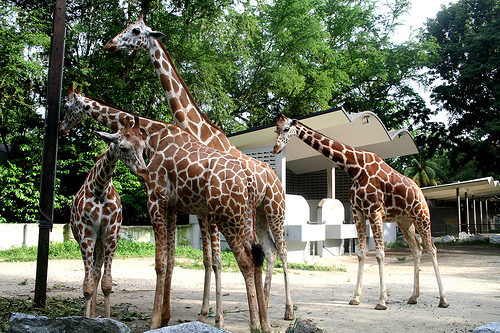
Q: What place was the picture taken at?
A: It was taken at the zoo.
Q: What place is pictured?
A: It is a zoo.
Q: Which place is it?
A: It is a zoo.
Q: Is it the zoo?
A: Yes, it is the zoo.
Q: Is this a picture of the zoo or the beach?
A: It is showing the zoo.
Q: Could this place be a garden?
A: No, it is a zoo.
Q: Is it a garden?
A: No, it is a zoo.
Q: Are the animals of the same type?
A: Yes, all the animals are giraffes.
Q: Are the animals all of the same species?
A: Yes, all the animals are giraffes.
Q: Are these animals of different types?
A: No, all the animals are giraffes.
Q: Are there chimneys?
A: No, there are no chimneys.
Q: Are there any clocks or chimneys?
A: No, there are no chimneys or clocks.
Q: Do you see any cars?
A: No, there are no cars.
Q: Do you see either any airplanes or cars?
A: No, there are no cars or airplanes.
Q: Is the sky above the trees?
A: Yes, the sky is above the trees.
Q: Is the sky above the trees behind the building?
A: Yes, the sky is above the trees.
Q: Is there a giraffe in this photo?
A: Yes, there are giraffes.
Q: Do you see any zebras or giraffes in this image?
A: Yes, there are giraffes.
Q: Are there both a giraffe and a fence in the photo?
A: Yes, there are both a giraffe and a fence.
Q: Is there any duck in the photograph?
A: No, there are no ducks.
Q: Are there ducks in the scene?
A: No, there are no ducks.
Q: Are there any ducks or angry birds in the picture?
A: No, there are no ducks or angry birds.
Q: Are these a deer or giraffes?
A: These are giraffes.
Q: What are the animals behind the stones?
A: The animals are giraffes.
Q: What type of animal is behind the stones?
A: The animals are giraffes.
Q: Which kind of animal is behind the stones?
A: The animals are giraffes.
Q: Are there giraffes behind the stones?
A: Yes, there are giraffes behind the stones.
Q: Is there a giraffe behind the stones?
A: Yes, there are giraffes behind the stones.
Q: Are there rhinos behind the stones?
A: No, there are giraffes behind the stones.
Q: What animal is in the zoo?
A: The giraffes are in the zoo.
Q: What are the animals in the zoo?
A: The animals are giraffes.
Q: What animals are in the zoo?
A: The animals are giraffes.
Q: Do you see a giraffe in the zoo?
A: Yes, there are giraffes in the zoo.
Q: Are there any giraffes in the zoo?
A: Yes, there are giraffes in the zoo.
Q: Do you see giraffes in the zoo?
A: Yes, there are giraffes in the zoo.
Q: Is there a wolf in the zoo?
A: No, there are giraffes in the zoo.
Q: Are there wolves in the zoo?
A: No, there are giraffes in the zoo.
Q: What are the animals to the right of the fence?
A: The animals are giraffes.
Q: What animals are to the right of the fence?
A: The animals are giraffes.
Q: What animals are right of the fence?
A: The animals are giraffes.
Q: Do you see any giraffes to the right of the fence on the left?
A: Yes, there are giraffes to the right of the fence.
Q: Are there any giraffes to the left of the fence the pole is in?
A: No, the giraffes are to the right of the fence.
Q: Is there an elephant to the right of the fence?
A: No, there are giraffes to the right of the fence.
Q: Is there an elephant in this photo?
A: No, there are no elephants.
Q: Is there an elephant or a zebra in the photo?
A: No, there are no elephants or zebras.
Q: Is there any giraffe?
A: Yes, there is a giraffe.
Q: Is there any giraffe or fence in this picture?
A: Yes, there is a giraffe.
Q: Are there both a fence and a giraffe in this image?
A: Yes, there are both a giraffe and a fence.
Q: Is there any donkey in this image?
A: No, there are no donkeys.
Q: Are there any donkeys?
A: No, there are no donkeys.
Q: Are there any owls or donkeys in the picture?
A: No, there are no donkeys or owls.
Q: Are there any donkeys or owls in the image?
A: No, there are no donkeys or owls.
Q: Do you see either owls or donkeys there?
A: No, there are no donkeys or owls.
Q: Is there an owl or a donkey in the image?
A: No, there are no donkeys or owls.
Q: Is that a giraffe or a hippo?
A: That is a giraffe.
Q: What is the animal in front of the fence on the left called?
A: The animal is a giraffe.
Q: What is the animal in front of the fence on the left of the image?
A: The animal is a giraffe.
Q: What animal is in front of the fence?
A: The animal is a giraffe.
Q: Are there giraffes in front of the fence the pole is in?
A: Yes, there is a giraffe in front of the fence.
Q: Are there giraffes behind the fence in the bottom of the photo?
A: No, the giraffe is in front of the fence.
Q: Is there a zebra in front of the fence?
A: No, there is a giraffe in front of the fence.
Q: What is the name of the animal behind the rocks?
A: The animal is a giraffe.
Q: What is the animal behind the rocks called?
A: The animal is a giraffe.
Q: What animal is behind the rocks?
A: The animal is a giraffe.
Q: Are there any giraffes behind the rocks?
A: Yes, there is a giraffe behind the rocks.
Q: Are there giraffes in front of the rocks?
A: No, the giraffe is behind the rocks.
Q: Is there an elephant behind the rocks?
A: No, there is a giraffe behind the rocks.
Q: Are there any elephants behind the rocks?
A: No, there is a giraffe behind the rocks.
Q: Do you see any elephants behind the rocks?
A: No, there is a giraffe behind the rocks.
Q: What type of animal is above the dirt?
A: The animal is a giraffe.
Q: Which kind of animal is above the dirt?
A: The animal is a giraffe.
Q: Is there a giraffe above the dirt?
A: Yes, there is a giraffe above the dirt.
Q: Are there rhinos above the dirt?
A: No, there is a giraffe above the dirt.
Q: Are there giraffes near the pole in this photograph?
A: Yes, there is a giraffe near the pole.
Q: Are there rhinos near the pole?
A: No, there is a giraffe near the pole.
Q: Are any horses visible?
A: No, there are no horses.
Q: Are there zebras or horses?
A: No, there are no horses or zebras.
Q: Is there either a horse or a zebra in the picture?
A: No, there are no horses or zebras.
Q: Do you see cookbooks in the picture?
A: No, there are no cookbooks.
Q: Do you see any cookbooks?
A: No, there are no cookbooks.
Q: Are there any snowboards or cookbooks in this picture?
A: No, there are no cookbooks or snowboards.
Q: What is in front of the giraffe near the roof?
A: The rocks are in front of the giraffe.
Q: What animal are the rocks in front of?
A: The rocks are in front of the giraffe.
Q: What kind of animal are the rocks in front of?
A: The rocks are in front of the giraffe.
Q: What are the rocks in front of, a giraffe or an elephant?
A: The rocks are in front of a giraffe.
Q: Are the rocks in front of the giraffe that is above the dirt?
A: Yes, the rocks are in front of the giraffe.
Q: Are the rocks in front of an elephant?
A: No, the rocks are in front of the giraffe.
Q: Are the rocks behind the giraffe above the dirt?
A: No, the rocks are in front of the giraffe.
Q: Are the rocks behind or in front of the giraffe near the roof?
A: The rocks are in front of the giraffe.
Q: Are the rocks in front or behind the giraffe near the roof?
A: The rocks are in front of the giraffe.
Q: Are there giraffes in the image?
A: Yes, there is a giraffe.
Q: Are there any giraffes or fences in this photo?
A: Yes, there is a giraffe.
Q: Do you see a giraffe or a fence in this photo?
A: Yes, there is a giraffe.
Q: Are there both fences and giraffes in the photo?
A: Yes, there are both a giraffe and a fence.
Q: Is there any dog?
A: No, there are no dogs.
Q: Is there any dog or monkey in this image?
A: No, there are no dogs or monkeys.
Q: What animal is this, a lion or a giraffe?
A: This is a giraffe.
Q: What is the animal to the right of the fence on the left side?
A: The animal is a giraffe.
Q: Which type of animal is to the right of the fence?
A: The animal is a giraffe.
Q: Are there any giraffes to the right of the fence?
A: Yes, there is a giraffe to the right of the fence.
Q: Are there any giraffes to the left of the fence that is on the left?
A: No, the giraffe is to the right of the fence.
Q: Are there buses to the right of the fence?
A: No, there is a giraffe to the right of the fence.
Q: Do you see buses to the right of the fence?
A: No, there is a giraffe to the right of the fence.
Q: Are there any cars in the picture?
A: No, there are no cars.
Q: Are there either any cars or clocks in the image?
A: No, there are no cars or clocks.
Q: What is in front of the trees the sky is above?
A: The building is in front of the trees.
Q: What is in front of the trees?
A: The building is in front of the trees.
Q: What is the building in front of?
A: The building is in front of the trees.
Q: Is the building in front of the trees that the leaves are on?
A: Yes, the building is in front of the trees.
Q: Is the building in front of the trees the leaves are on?
A: Yes, the building is in front of the trees.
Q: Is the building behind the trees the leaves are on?
A: No, the building is in front of the trees.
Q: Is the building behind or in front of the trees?
A: The building is in front of the trees.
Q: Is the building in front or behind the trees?
A: The building is in front of the trees.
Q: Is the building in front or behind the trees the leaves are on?
A: The building is in front of the trees.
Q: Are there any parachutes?
A: No, there are no parachutes.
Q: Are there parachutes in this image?
A: No, there are no parachutes.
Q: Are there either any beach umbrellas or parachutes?
A: No, there are no parachutes or beach umbrellas.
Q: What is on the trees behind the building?
A: The leaves are on the trees.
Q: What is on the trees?
A: The leaves are on the trees.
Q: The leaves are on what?
A: The leaves are on the trees.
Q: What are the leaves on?
A: The leaves are on the trees.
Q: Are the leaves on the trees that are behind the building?
A: Yes, the leaves are on the trees.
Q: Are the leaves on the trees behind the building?
A: Yes, the leaves are on the trees.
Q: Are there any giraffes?
A: Yes, there is a giraffe.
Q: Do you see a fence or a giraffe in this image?
A: Yes, there is a giraffe.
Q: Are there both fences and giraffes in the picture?
A: Yes, there are both a giraffe and a fence.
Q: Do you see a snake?
A: No, there are no snakes.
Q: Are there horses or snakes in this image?
A: No, there are no snakes or horses.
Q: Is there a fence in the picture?
A: Yes, there is a fence.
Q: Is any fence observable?
A: Yes, there is a fence.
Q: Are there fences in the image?
A: Yes, there is a fence.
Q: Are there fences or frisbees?
A: Yes, there is a fence.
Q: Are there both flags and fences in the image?
A: No, there is a fence but no flags.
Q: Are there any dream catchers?
A: No, there are no dream catchers.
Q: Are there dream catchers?
A: No, there are no dream catchers.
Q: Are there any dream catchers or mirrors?
A: No, there are no dream catchers or mirrors.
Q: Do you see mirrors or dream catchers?
A: No, there are no dream catchers or mirrors.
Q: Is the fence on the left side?
A: Yes, the fence is on the left of the image.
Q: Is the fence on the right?
A: No, the fence is on the left of the image.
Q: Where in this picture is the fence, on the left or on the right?
A: The fence is on the left of the image.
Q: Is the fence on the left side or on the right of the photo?
A: The fence is on the left of the image.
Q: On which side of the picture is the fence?
A: The fence is on the left of the image.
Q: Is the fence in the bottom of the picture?
A: Yes, the fence is in the bottom of the image.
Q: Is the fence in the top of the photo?
A: No, the fence is in the bottom of the image.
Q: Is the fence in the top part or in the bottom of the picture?
A: The fence is in the bottom of the image.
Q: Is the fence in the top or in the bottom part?
A: The fence is in the bottom of the image.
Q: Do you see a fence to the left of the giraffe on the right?
A: Yes, there is a fence to the left of the giraffe.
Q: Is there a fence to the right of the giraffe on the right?
A: No, the fence is to the left of the giraffe.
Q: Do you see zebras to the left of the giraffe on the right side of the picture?
A: No, there is a fence to the left of the giraffe.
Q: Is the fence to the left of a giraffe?
A: Yes, the fence is to the left of a giraffe.